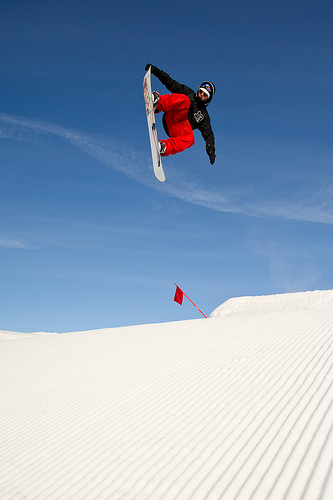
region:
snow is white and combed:
[62, 349, 331, 474]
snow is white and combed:
[30, 399, 232, 488]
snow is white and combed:
[43, 346, 267, 486]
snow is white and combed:
[111, 371, 280, 493]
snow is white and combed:
[7, 348, 271, 480]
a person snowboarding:
[127, 43, 247, 191]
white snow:
[37, 333, 330, 498]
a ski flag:
[162, 281, 246, 349]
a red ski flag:
[157, 272, 229, 366]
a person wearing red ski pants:
[124, 41, 234, 169]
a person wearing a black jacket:
[104, 31, 267, 180]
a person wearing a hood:
[186, 72, 227, 133]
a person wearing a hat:
[182, 78, 230, 120]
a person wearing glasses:
[186, 78, 222, 110]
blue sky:
[2, 45, 321, 290]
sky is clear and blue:
[47, 314, 155, 324]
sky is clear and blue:
[52, 298, 158, 315]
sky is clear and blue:
[31, 287, 193, 324]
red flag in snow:
[164, 271, 221, 323]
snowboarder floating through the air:
[127, 54, 233, 189]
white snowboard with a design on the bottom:
[138, 66, 168, 185]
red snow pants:
[156, 91, 198, 161]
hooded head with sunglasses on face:
[194, 78, 221, 104]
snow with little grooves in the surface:
[143, 363, 242, 467]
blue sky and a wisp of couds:
[39, 101, 116, 209]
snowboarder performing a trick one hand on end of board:
[131, 52, 236, 182]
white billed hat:
[198, 84, 213, 96]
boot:
[155, 137, 172, 159]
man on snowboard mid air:
[116, 51, 248, 202]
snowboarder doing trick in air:
[133, 56, 221, 173]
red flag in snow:
[156, 270, 205, 323]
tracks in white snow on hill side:
[106, 414, 142, 444]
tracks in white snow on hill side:
[237, 468, 268, 492]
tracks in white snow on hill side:
[237, 373, 266, 397]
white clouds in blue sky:
[92, 221, 112, 240]